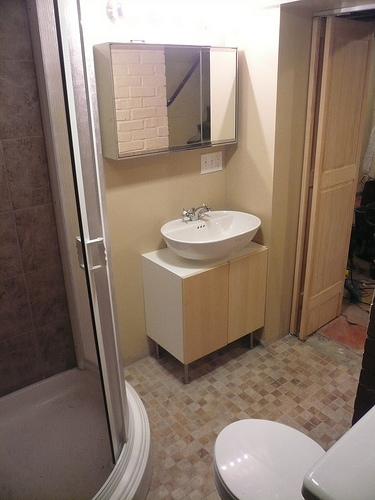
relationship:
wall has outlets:
[86, 0, 272, 387] [199, 143, 227, 175]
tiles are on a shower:
[0, 4, 81, 394] [0, 0, 150, 495]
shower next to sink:
[0, 0, 150, 495] [162, 204, 265, 265]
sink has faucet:
[157, 205, 261, 266] [177, 200, 210, 223]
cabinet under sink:
[143, 233, 272, 369] [155, 208, 262, 263]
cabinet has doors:
[140, 247, 228, 366] [188, 249, 270, 362]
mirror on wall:
[164, 45, 210, 149] [86, 0, 272, 387]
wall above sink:
[86, 0, 272, 387] [159, 204, 257, 263]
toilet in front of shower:
[214, 402, 371, 498] [0, 0, 150, 495]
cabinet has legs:
[143, 233, 272, 369] [152, 328, 257, 385]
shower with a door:
[0, 0, 150, 499] [1, 2, 109, 488]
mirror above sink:
[164, 45, 210, 149] [134, 182, 278, 303]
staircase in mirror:
[187, 102, 209, 144] [163, 43, 210, 149]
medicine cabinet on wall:
[92, 41, 237, 158] [88, 0, 226, 367]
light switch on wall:
[199, 151, 222, 172] [88, 0, 226, 367]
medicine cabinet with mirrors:
[92, 41, 238, 159] [109, 43, 236, 156]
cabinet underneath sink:
[140, 247, 228, 366] [158, 205, 260, 266]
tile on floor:
[181, 394, 193, 404] [120, 334, 364, 497]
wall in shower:
[0, 0, 81, 396] [0, 0, 150, 495]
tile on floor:
[169, 420, 181, 430] [120, 334, 364, 497]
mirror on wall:
[163, 43, 210, 149] [88, 0, 226, 367]